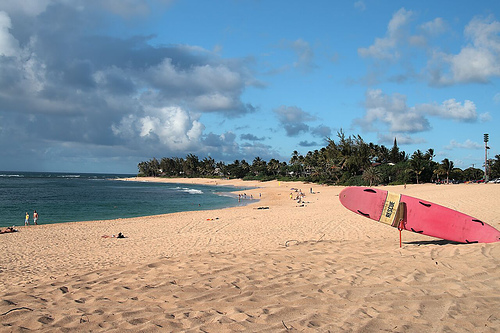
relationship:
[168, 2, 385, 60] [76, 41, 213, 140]
sky behind clouds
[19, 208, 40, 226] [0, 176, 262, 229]
people next to water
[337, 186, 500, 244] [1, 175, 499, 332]
board out of sand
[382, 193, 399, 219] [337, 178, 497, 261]
writing on surfboard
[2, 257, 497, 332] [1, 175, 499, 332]
foot prints in sand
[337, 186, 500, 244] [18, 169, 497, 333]
board on beach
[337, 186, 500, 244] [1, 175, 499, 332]
board on sand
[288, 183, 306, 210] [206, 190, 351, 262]
people on beach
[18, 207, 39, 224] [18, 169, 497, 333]
people on beach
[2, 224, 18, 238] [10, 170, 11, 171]
person on beach